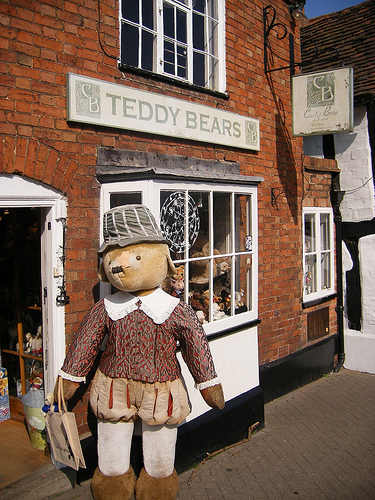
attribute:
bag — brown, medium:
[44, 373, 86, 471]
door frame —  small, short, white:
[0, 138, 94, 477]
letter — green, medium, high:
[104, 93, 120, 115]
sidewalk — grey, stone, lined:
[106, 383, 342, 495]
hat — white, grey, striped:
[95, 197, 182, 252]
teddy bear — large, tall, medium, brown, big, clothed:
[54, 203, 224, 498]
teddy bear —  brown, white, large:
[95, 207, 172, 293]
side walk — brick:
[293, 380, 338, 490]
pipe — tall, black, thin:
[326, 173, 348, 375]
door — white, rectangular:
[2, 171, 80, 464]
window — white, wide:
[119, 0, 227, 95]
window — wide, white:
[109, 188, 252, 325]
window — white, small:
[299, 208, 338, 300]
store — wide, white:
[1, 0, 345, 494]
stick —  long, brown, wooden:
[187, 420, 260, 486]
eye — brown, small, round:
[131, 249, 150, 267]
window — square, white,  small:
[303, 208, 336, 304]